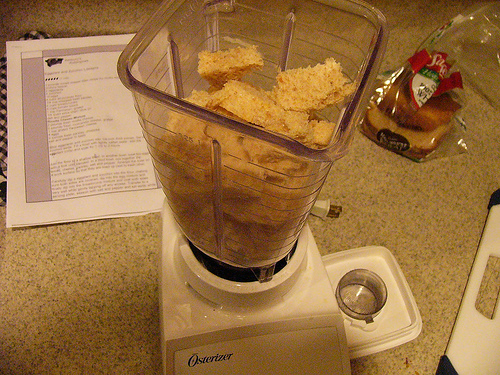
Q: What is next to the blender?
A: The top of the blender.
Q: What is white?
A: Base of blender.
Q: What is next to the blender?
A: Sheet of paper.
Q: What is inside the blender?
A: Bread.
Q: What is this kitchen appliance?
A: Blender.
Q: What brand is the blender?
A: Osterizer.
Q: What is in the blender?
A: Bread.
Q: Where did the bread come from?
A: Bag on counter.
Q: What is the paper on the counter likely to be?
A: Recipe.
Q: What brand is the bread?
A: Sara lee.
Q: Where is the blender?
A: Counter.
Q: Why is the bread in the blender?
A: Make crumbs.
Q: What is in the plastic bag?
A: Bread.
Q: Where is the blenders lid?
A: On the counter.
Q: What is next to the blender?
A: Paper.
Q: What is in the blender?
A: Bread.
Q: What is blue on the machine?
A: Writing.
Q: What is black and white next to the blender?
A: A cutting board.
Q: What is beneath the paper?
A: A checkered cloth.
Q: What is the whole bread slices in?
A: A bag.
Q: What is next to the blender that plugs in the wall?
A: A power cord.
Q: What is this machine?
A: A blender.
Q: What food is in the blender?
A: Bread.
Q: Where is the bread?
A: In blender.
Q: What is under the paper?
A: Blue and white dish towel.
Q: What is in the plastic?
A: Bread.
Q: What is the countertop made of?
A: Speckled granite.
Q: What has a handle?
A: Cutting board.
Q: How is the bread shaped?
A: Torn pieces.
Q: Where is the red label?
A: Bread bag.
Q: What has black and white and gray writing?
A: Paper.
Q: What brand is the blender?
A: Osterizer.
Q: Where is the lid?
A: On the table.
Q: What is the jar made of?
A: Glass.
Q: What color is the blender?
A: White.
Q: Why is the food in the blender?
A: To mix.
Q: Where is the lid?
A: On the counter.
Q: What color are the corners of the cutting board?
A: Black.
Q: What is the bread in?
A: A bag.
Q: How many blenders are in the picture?
A: One.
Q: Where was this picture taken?
A: Inside a house.